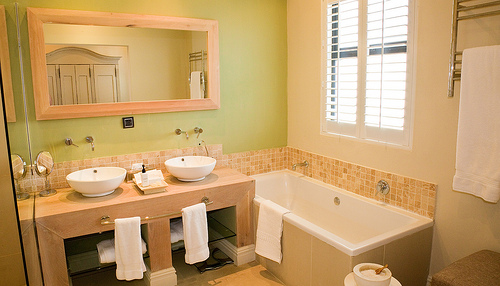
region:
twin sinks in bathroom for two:
[61, 148, 218, 187]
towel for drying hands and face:
[111, 218, 138, 283]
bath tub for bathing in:
[252, 167, 410, 267]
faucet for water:
[290, 155, 311, 175]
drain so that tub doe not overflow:
[329, 193, 344, 206]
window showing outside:
[323, 2, 405, 146]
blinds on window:
[318, 3, 413, 145]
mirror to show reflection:
[23, 11, 219, 106]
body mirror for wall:
[0, 0, 45, 282]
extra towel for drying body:
[458, 41, 498, 199]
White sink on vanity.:
[163, 155, 217, 180]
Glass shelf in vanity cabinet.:
[165, 217, 236, 256]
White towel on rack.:
[175, 203, 213, 265]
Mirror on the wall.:
[26, 5, 226, 122]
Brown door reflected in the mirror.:
[45, 42, 138, 104]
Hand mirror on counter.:
[33, 148, 62, 201]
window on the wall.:
[318, 0, 418, 157]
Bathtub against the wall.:
[240, 161, 433, 284]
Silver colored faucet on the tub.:
[288, 156, 310, 176]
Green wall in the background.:
[13, 2, 290, 165]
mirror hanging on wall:
[26, 7, 221, 119]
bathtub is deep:
[245, 166, 435, 283]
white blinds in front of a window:
[325, 0, 408, 142]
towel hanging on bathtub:
[253, 198, 288, 254]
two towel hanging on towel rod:
[96, 199, 214, 279]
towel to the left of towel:
[113, 218, 150, 278]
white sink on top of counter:
[164, 153, 214, 182]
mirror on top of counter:
[36, 150, 57, 197]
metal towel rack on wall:
[448, 0, 498, 98]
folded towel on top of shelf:
[98, 235, 147, 260]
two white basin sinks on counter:
[47, 132, 237, 209]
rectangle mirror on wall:
[17, 13, 247, 131]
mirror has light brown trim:
[17, 3, 243, 132]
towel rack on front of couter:
[94, 189, 216, 236]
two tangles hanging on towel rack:
[100, 188, 237, 284]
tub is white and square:
[218, 143, 440, 284]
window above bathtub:
[300, 1, 430, 160]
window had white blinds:
[305, 5, 425, 145]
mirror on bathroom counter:
[20, 137, 62, 207]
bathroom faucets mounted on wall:
[45, 114, 242, 160]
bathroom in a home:
[7, 2, 496, 283]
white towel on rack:
[185, 204, 217, 265]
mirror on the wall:
[49, 24, 207, 104]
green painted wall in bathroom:
[237, 20, 289, 142]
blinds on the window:
[367, 4, 405, 124]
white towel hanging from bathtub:
[252, 198, 285, 262]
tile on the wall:
[318, 161, 345, 184]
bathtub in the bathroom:
[252, 166, 433, 259]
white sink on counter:
[166, 149, 227, 179]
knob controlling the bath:
[372, 176, 392, 202]